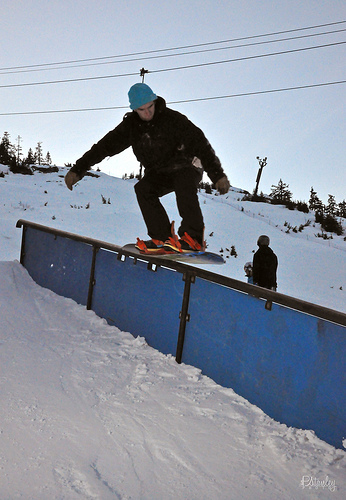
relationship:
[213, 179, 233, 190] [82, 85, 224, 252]
gloves on snowboarder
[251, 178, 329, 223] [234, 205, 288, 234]
trees lining slope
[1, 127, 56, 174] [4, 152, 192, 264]
pine trees on hilltop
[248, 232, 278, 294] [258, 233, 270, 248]
skier wearing ski helmet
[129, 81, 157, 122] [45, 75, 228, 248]
head of person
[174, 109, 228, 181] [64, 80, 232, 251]
arm of man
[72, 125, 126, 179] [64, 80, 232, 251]
arm of man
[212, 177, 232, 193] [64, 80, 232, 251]
hand of man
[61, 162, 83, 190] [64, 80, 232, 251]
hand of man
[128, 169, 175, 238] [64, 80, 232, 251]
leg of man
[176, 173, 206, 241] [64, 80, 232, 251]
leg of man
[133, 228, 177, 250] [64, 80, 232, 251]
foot of man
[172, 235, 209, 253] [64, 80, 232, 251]
foot of man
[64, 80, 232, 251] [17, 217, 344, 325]
man riding rail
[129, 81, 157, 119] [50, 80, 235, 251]
head of man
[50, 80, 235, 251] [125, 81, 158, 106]
man wearing cap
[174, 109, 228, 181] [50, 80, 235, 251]
arm of man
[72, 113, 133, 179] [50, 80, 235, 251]
arm of man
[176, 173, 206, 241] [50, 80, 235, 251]
leg of man